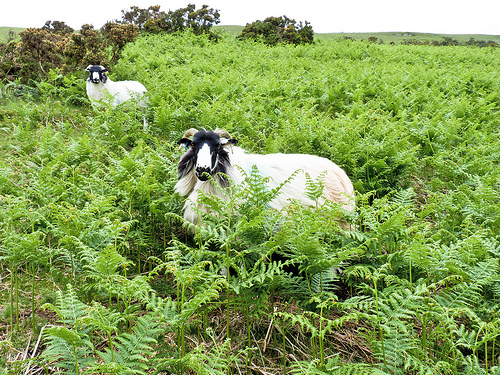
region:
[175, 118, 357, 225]
A black and white goat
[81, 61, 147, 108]
Black and white goat in the distace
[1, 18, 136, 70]
A bush in the background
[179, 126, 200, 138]
One of the goat's horns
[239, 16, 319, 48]
A tree in the distance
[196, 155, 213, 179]
The closest goat's snout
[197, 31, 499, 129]
Large section of leafy plants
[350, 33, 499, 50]
A distant tree line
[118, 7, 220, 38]
A tree behind the goats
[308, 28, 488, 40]
A hill in the distance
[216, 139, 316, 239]
the goat's fur is white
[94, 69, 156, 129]
the goat's fur is white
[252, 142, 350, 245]
the goat's fur is white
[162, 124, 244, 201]
the goat's face is black and white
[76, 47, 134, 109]
the goat's face is black and white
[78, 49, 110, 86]
the goat's face is black and white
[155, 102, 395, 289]
goat in a field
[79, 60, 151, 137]
goat in a field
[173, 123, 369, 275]
goat with black face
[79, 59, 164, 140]
goat with black face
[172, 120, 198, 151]
horn on a goat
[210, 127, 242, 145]
horn on a goat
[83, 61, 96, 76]
horn on a goat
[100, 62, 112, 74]
horn on a goat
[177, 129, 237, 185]
black and white goat face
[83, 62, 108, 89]
black and white goat face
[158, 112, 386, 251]
a sheep among the grass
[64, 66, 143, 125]
a sheep among the grass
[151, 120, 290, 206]
sheep's face is black and white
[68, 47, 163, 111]
sheep's face is black and white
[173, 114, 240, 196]
sheep's face is black and white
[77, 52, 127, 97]
sheep's face is black and white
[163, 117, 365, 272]
sheep in field of ferns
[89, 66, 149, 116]
sheep in field of ferns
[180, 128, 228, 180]
head of the sheep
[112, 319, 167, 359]
green fern in field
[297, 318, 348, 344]
green fern in field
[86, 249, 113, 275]
green fern in field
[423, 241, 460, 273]
green fern in field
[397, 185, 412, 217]
green fern in field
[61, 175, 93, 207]
green fern in field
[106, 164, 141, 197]
green fern in field